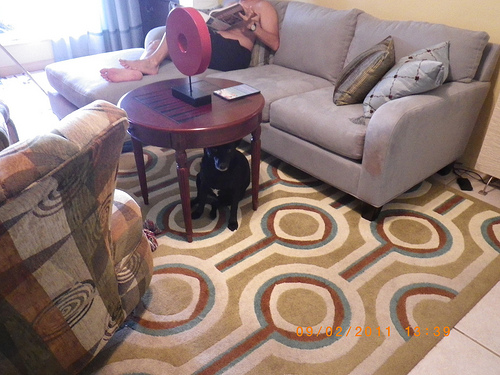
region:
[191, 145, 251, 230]
A dog under the table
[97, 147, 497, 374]
A rug on the floor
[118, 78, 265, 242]
A table above the dog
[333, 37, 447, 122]
Pillows on the couch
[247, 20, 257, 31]
The man is wearing a watch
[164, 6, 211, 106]
A piece of art on the table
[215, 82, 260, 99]
A DVD on the table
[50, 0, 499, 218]
A couch beneath the man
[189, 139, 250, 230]
The dog is sitting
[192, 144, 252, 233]
A black dog under a table.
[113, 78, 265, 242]
A round table with a dog under it.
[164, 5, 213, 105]
A red and black piece of art on a table top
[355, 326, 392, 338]
Orange year 2011.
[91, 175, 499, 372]
A brown, red and blue area rug.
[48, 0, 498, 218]
A grey chaise lounge.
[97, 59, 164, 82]
Feet of a man on the couch.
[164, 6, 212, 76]
A round red circle with a hole in it.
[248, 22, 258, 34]
A black and white watch on a man's wrist.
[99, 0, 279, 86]
A man with no shirt on on the couch.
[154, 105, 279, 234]
dog under the table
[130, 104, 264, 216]
table is brown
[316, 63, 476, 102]
two pillows on the sofa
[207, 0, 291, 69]
person reading a book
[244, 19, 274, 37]
watch on left wrist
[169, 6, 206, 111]
red circle with black base on table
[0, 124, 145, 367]
chair with green and brown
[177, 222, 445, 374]
rug on floor has circles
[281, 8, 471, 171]
gray sofa the person is on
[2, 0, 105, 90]
sunlight reflecting in window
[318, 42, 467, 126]
two pillows on the couch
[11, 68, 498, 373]
rug on the floor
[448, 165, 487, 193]
black cords on the floor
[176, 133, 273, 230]
dog sitting under the table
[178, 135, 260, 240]
black fur on the dog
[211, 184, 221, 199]
white spot on the dog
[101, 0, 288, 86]
man sitting on the couch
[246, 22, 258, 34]
watch around the wrist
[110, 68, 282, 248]
small brown table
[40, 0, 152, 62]
floor length curtains on the window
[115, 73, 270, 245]
a dog under the side table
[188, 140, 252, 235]
a dog on the rug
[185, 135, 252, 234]
a black dog under the table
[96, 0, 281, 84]
a person on the couch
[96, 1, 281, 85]
a person reading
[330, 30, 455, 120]
pillows on the couch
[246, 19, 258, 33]
a watch the person is wearing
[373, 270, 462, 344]
a pattern on the rug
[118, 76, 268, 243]
a table on the rug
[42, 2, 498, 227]
a gray couch in the room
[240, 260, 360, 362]
colorful design on the green carpet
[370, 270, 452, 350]
colorful design on the green carpet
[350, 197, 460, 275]
colorful design on the green carpet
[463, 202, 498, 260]
colorful design on the green carpet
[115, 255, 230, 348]
colorful design on the green carpet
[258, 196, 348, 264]
colorful design on the green carpet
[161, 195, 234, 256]
colorful design on the green carpet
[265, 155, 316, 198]
colorful design on the green carpet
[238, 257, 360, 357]
A circle on the rug.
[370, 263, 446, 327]
A circle on the rug.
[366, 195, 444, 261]
A circle on the rug.